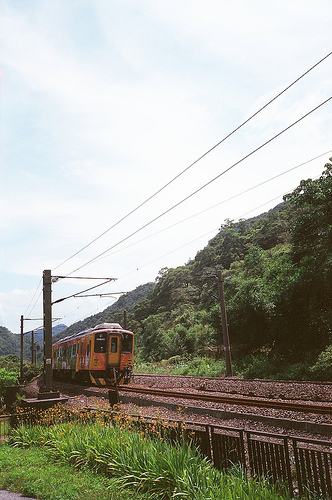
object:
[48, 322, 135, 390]
train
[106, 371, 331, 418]
track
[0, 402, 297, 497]
grass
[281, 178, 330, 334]
tree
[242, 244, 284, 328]
tree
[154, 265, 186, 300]
tree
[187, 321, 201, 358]
tree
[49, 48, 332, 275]
wire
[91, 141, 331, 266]
wire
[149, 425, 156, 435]
flower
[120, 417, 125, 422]
flower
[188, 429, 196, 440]
flower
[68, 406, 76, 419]
flower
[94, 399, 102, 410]
flower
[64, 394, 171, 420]
gravel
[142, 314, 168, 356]
tree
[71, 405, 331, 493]
gate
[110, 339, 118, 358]
person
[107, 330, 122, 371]
door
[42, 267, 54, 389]
telephone post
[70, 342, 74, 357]
window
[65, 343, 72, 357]
window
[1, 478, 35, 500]
cement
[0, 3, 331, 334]
sky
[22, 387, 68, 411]
base